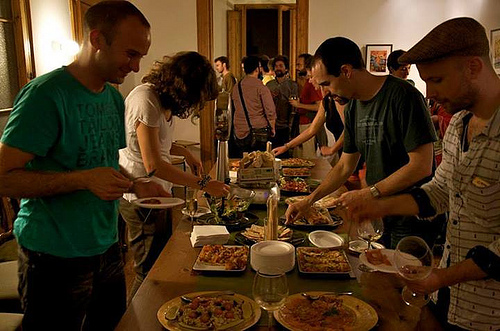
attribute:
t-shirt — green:
[1, 69, 126, 255]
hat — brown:
[398, 16, 492, 60]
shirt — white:
[124, 84, 174, 196]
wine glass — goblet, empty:
[393, 234, 433, 305]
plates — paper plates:
[249, 240, 295, 274]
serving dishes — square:
[192, 243, 250, 274]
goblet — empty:
[252, 267, 290, 330]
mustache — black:
[271, 54, 290, 78]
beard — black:
[333, 93, 350, 106]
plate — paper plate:
[134, 193, 185, 208]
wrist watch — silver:
[369, 184, 380, 199]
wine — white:
[400, 261, 429, 276]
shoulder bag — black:
[237, 78, 273, 148]